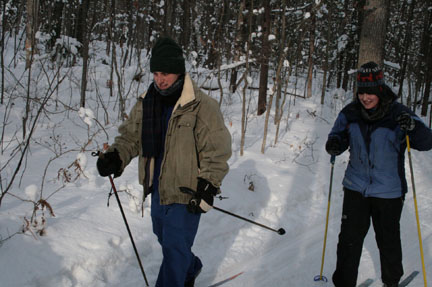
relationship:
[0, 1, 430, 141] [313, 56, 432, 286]
trees behind woman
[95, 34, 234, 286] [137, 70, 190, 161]
man wearing scarf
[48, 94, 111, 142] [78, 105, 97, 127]
branch covered in snow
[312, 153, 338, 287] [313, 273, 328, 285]
ski stick has bottom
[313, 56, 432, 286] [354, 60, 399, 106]
woman wearing hat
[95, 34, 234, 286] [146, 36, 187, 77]
man wearing hat